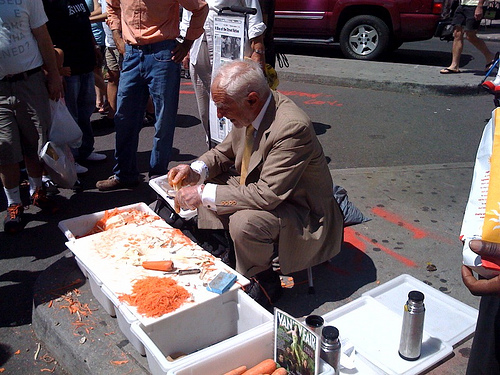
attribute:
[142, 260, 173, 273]
carrot — orange, peeled, pink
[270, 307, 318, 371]
magazine — green, white, display, vait fair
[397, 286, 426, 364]
thermo — stainle steel, large, shiny, black, silver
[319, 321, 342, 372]
thermo — stainle steel, silver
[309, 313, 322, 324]
thermo — stainle steel, silver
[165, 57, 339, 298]
man — old, sitting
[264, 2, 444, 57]
vehicle — maroon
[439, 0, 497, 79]
woman — walking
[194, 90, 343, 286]
suit — tan, brown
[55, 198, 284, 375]
boxes — white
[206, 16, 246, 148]
newspaper — hanging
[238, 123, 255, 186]
tie — gold, yellow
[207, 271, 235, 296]
sponge — blue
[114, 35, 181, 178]
jeans — blue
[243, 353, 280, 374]
carrot — peeled, pink, orage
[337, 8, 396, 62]
wheel — black, silver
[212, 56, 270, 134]
head — bald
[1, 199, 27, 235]
sneaker — blue, orage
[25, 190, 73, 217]
sneaker — blue, orage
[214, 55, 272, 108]
hair — white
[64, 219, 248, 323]
cutting board — white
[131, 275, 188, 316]
carrot — orange, peeled, pink, shaved, shredded